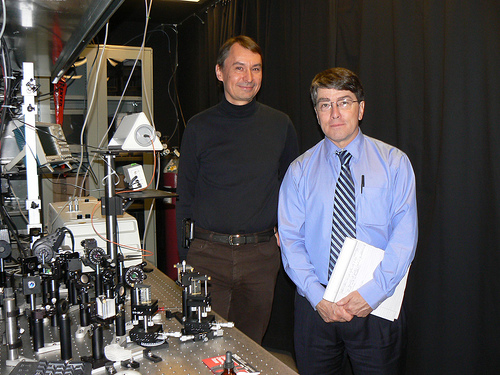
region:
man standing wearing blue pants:
[271, 60, 428, 369]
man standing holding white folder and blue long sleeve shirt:
[275, 58, 417, 363]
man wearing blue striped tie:
[275, 58, 420, 372]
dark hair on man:
[310, 63, 365, 105]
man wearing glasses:
[280, 64, 425, 374]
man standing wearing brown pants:
[178, 32, 310, 352]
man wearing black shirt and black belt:
[167, 29, 324, 339]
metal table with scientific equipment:
[5, 0, 295, 374]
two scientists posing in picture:
[171, 28, 426, 370]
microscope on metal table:
[175, 257, 221, 348]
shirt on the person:
[277, 140, 432, 302]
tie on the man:
[324, 148, 365, 292]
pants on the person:
[294, 285, 405, 374]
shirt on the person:
[182, 99, 306, 232]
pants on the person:
[176, 239, 279, 329]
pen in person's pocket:
[351, 168, 364, 195]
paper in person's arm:
[313, 222, 418, 325]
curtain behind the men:
[201, 5, 472, 371]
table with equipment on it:
[138, 265, 290, 370]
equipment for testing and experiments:
[3, 50, 240, 359]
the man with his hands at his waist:
[281, 54, 413, 374]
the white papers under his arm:
[323, 237, 410, 324]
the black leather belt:
[191, 223, 268, 248]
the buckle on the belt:
[229, 230, 242, 247]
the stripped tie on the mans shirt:
[332, 145, 356, 236]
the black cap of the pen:
[354, 172, 367, 193]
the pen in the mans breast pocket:
[356, 168, 388, 225]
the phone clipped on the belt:
[176, 217, 197, 247]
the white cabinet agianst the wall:
[81, 40, 156, 108]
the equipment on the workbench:
[4, 229, 215, 361]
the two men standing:
[177, 35, 417, 372]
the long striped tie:
[326, 150, 356, 280]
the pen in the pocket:
[360, 173, 365, 195]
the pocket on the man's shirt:
[358, 185, 389, 226]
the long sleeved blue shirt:
[277, 127, 417, 312]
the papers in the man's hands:
[321, 235, 411, 320]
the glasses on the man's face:
[314, 97, 361, 110]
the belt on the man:
[187, 228, 274, 245]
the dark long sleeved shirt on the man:
[176, 99, 299, 262]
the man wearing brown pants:
[175, 35, 299, 344]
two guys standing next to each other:
[175, 38, 426, 366]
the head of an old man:
[314, 71, 371, 143]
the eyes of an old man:
[310, 95, 363, 110]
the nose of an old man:
[327, 109, 351, 124]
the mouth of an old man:
[321, 111, 355, 131]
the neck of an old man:
[310, 122, 362, 149]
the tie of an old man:
[314, 148, 369, 253]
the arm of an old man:
[360, 153, 441, 283]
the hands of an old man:
[307, 289, 375, 323]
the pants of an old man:
[182, 226, 282, 328]